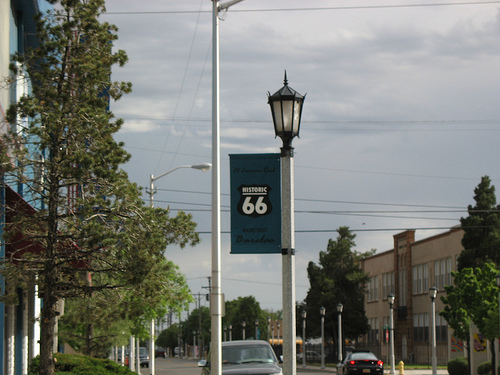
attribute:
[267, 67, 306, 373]
street light — tall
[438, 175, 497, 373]
tree building — Green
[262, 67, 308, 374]
street light — tall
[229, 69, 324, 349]
light — tall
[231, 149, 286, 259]
sign — Route 66, historic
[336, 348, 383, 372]
car — black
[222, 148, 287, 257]
sign — blue, black, white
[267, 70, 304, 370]
streetlight — tall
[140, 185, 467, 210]
wire — black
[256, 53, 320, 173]
lamps — Black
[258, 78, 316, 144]
glass — white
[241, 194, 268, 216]
numbers — white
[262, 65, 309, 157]
light — black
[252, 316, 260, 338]
light — tall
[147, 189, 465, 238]
wires — black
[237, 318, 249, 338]
street light — tall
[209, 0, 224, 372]
white pole — Tall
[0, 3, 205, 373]
tree — GREEN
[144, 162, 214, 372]
street light — tall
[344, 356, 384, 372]
lights — red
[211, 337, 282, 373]
car — parked